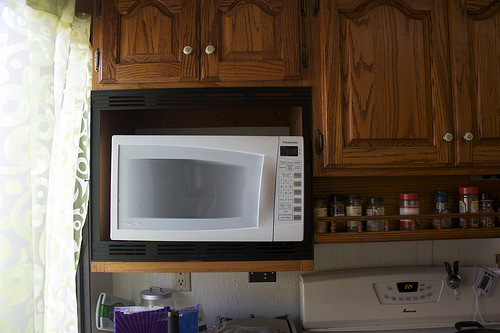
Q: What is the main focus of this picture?
A: Microwave.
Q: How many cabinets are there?
A: 4.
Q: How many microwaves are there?
A: 1.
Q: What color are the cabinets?
A: Brown.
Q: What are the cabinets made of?
A: Wood.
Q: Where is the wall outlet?
A: Below the microwave.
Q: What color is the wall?
A: White.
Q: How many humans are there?
A: 0.